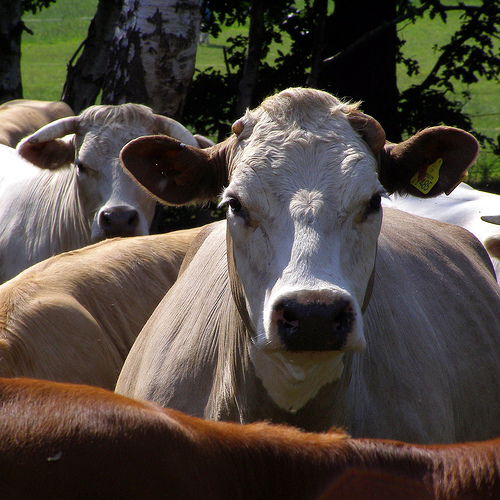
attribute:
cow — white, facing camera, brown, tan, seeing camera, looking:
[114, 87, 495, 440]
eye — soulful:
[218, 189, 249, 227]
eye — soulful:
[365, 190, 384, 212]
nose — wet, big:
[274, 291, 356, 351]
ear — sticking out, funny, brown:
[119, 134, 229, 207]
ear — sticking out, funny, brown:
[390, 125, 480, 199]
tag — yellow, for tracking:
[409, 158, 443, 196]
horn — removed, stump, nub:
[230, 119, 256, 139]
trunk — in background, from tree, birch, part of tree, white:
[64, 4, 203, 124]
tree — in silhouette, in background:
[264, 7, 496, 142]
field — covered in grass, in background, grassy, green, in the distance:
[7, 5, 495, 192]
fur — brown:
[124, 88, 493, 433]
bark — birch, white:
[110, 3, 197, 115]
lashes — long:
[215, 194, 237, 211]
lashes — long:
[371, 186, 393, 203]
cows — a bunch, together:
[5, 87, 493, 486]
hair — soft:
[242, 85, 364, 131]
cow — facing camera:
[6, 105, 216, 280]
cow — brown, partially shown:
[9, 377, 494, 491]